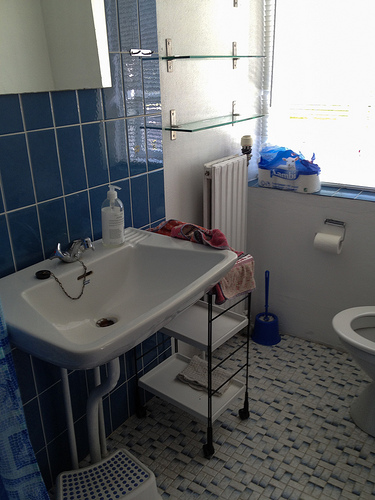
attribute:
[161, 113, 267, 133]
shelf — glass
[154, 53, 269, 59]
shelf — glass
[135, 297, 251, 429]
shelf — white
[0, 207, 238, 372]
sink — clean, white, wide, flat, square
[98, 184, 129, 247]
bottle — plastic, small, white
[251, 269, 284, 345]
brush — blue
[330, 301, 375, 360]
seat — white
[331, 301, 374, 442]
toilet — white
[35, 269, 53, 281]
stopper — black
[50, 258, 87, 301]
chain — black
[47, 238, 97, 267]
faucet — steel, stainless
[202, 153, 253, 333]
radiator — white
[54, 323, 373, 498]
tiles — square, blue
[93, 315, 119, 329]
hole — large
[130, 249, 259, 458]
holder — wheeled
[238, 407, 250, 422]
wheel — black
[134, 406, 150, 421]
wheel — black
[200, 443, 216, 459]
wheel — black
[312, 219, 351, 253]
holder — white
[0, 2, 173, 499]
tiles — blue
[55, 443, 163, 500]
stool — spotted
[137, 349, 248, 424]
tray — white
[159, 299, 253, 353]
tray — white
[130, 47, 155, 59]
hook — silver